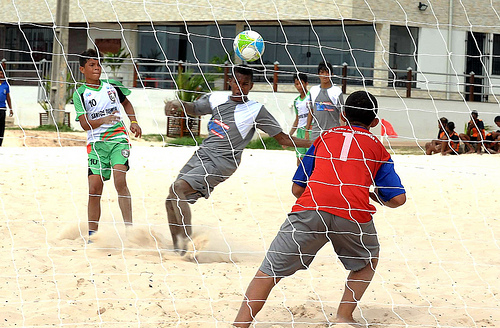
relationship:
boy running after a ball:
[197, 62, 270, 186] [228, 27, 274, 59]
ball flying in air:
[228, 27, 274, 59] [194, 16, 211, 31]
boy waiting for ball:
[197, 62, 270, 186] [228, 27, 274, 59]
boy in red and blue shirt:
[197, 62, 270, 186] [291, 123, 404, 209]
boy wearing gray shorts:
[197, 62, 270, 186] [183, 145, 225, 195]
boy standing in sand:
[197, 62, 270, 186] [428, 190, 464, 244]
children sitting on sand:
[432, 115, 495, 146] [428, 190, 464, 244]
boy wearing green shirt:
[197, 62, 270, 186] [76, 86, 138, 139]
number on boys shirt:
[339, 130, 354, 162] [291, 123, 404, 209]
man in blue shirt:
[0, 67, 14, 147] [1, 82, 10, 108]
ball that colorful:
[228, 27, 274, 59] [239, 40, 264, 48]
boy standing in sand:
[73, 48, 143, 244] [428, 190, 464, 244]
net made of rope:
[19, 31, 68, 116] [154, 27, 193, 38]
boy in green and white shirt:
[73, 46, 147, 178] [76, 86, 138, 139]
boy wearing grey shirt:
[197, 62, 270, 186] [203, 98, 251, 147]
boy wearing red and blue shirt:
[301, 85, 404, 293] [291, 123, 404, 209]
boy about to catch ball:
[197, 62, 270, 186] [228, 27, 274, 59]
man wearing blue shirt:
[0, 67, 14, 147] [1, 82, 10, 108]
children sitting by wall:
[432, 115, 495, 146] [397, 100, 427, 131]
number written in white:
[339, 130, 354, 162] [344, 149, 349, 162]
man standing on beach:
[0, 67, 14, 147] [2, 158, 46, 229]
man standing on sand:
[0, 67, 14, 147] [428, 190, 464, 244]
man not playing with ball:
[0, 67, 14, 147] [228, 27, 274, 59]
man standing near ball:
[0, 67, 14, 147] [228, 27, 274, 59]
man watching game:
[0, 67, 14, 147] [63, 27, 468, 203]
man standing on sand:
[1, 60, 21, 168] [428, 190, 464, 244]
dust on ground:
[112, 223, 166, 242] [248, 174, 266, 218]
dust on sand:
[112, 223, 166, 242] [428, 190, 464, 244]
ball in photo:
[228, 27, 274, 59] [8, 17, 482, 300]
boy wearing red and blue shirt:
[197, 62, 270, 186] [291, 123, 404, 209]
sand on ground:
[428, 190, 464, 244] [248, 174, 266, 218]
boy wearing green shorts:
[73, 46, 147, 178] [86, 140, 140, 173]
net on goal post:
[19, 31, 68, 116] [44, 10, 67, 116]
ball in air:
[228, 27, 274, 59] [194, 16, 211, 31]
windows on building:
[311, 22, 373, 63] [257, 2, 340, 18]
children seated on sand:
[432, 115, 495, 146] [428, 190, 464, 244]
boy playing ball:
[73, 48, 143, 244] [228, 27, 274, 59]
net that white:
[19, 31, 68, 116] [344, 149, 349, 162]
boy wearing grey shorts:
[197, 62, 270, 186] [183, 145, 225, 195]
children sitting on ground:
[432, 115, 495, 146] [248, 174, 266, 218]